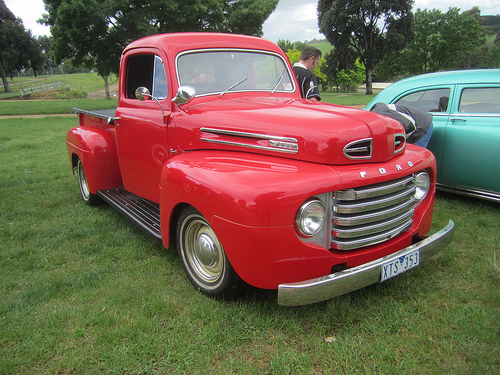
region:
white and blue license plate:
[349, 250, 429, 309]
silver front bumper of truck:
[247, 217, 467, 348]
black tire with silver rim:
[144, 217, 231, 333]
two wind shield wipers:
[191, 66, 299, 118]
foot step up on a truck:
[54, 163, 169, 267]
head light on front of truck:
[393, 165, 442, 213]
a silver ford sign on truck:
[343, 153, 426, 199]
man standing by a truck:
[131, 47, 350, 226]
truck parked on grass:
[2, 162, 303, 358]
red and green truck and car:
[134, 60, 495, 274]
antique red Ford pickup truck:
[61, 28, 467, 303]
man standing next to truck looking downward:
[289, 40, 331, 102]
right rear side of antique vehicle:
[353, 63, 498, 205]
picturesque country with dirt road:
[8, 17, 115, 106]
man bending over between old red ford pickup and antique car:
[352, 96, 447, 151]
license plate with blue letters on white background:
[374, 243, 434, 290]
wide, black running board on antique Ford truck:
[81, 177, 198, 249]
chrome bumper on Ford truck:
[267, 220, 499, 308]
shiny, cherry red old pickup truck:
[61, 27, 453, 311]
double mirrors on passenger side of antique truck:
[125, 80, 205, 137]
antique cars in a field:
[30, 17, 490, 322]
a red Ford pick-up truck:
[57, 23, 474, 323]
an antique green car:
[367, 62, 498, 200]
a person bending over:
[365, 97, 446, 174]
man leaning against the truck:
[288, 35, 335, 114]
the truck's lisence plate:
[378, 244, 428, 289]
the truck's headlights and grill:
[290, 169, 437, 263]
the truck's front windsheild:
[165, 41, 302, 109]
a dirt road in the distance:
[4, 76, 133, 128]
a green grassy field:
[7, 111, 492, 371]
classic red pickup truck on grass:
[62, 33, 458, 305]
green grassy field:
[0, 115, 491, 370]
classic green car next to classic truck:
[357, 66, 494, 196]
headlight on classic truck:
[295, 200, 325, 235]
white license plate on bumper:
[380, 250, 416, 280]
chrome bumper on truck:
[272, 215, 452, 305]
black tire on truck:
[170, 205, 225, 296]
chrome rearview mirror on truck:
[131, 81, 163, 118]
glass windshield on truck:
[172, 45, 292, 100]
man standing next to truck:
[291, 42, 322, 98]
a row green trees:
[2, 0, 495, 117]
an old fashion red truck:
[65, 26, 459, 311]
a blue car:
[357, 65, 499, 204]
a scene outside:
[5, 0, 497, 373]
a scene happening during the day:
[6, 4, 496, 374]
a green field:
[2, 97, 498, 374]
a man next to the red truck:
[279, 35, 328, 117]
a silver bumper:
[272, 215, 460, 312]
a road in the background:
[62, 76, 126, 101]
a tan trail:
[2, 106, 82, 125]